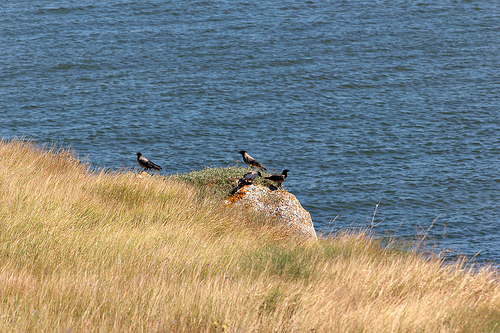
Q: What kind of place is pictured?
A: It is a field.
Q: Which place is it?
A: It is a field.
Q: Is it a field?
A: Yes, it is a field.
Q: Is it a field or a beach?
A: It is a field.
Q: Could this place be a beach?
A: No, it is a field.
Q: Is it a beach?
A: No, it is a field.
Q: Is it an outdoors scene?
A: Yes, it is outdoors.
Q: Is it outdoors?
A: Yes, it is outdoors.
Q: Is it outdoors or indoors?
A: It is outdoors.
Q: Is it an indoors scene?
A: No, it is outdoors.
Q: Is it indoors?
A: No, it is outdoors.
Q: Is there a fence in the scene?
A: No, there are no fences.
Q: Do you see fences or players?
A: No, there are no fences or players.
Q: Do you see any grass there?
A: Yes, there is grass.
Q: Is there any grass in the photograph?
A: Yes, there is grass.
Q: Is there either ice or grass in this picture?
A: Yes, there is grass.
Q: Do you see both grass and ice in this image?
A: No, there is grass but no ice.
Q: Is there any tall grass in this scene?
A: Yes, there is tall grass.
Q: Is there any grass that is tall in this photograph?
A: Yes, there is tall grass.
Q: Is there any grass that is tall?
A: Yes, there is grass that is tall.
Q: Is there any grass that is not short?
A: Yes, there is tall grass.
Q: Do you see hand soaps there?
A: No, there are no hand soaps.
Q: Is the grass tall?
A: Yes, the grass is tall.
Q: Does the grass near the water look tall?
A: Yes, the grass is tall.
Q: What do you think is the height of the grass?
A: The grass is tall.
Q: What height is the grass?
A: The grass is tall.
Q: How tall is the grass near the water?
A: The grass is tall.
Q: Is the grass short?
A: No, the grass is tall.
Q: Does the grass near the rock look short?
A: No, the grass is tall.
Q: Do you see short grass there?
A: No, there is grass but it is tall.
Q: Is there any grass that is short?
A: No, there is grass but it is tall.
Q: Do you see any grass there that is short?
A: No, there is grass but it is tall.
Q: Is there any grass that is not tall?
A: No, there is grass but it is tall.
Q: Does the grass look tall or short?
A: The grass is tall.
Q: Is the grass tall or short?
A: The grass is tall.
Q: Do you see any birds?
A: Yes, there is a bird.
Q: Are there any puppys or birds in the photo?
A: Yes, there is a bird.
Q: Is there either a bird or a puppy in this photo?
A: Yes, there is a bird.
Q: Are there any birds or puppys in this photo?
A: Yes, there is a bird.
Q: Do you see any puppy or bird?
A: Yes, there is a bird.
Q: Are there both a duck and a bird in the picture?
A: No, there is a bird but no ducks.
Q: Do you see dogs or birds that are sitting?
A: Yes, the bird is sitting.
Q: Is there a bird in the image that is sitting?
A: Yes, there is a bird that is sitting.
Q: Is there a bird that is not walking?
A: Yes, there is a bird that is sitting.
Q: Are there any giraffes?
A: No, there are no giraffes.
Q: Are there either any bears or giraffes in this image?
A: No, there are no giraffes or bears.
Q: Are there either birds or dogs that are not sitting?
A: No, there is a bird but it is sitting.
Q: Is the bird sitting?
A: Yes, the bird is sitting.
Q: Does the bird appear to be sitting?
A: Yes, the bird is sitting.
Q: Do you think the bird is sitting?
A: Yes, the bird is sitting.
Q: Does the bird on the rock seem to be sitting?
A: Yes, the bird is sitting.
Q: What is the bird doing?
A: The bird is sitting.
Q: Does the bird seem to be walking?
A: No, the bird is sitting.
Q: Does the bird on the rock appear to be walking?
A: No, the bird is sitting.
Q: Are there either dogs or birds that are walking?
A: No, there is a bird but it is sitting.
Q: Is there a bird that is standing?
A: No, there is a bird but it is sitting.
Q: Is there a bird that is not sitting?
A: No, there is a bird but it is sitting.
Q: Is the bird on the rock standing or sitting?
A: The bird is sitting.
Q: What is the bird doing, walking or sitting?
A: The bird is sitting.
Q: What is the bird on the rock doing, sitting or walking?
A: The bird is sitting.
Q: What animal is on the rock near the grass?
A: The bird is on the rock.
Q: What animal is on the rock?
A: The bird is on the rock.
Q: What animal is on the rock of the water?
A: The animal is a bird.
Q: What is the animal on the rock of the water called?
A: The animal is a bird.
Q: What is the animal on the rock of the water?
A: The animal is a bird.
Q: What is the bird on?
A: The bird is on the rock.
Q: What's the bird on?
A: The bird is on the rock.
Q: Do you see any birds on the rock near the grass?
A: Yes, there is a bird on the rock.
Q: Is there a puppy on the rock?
A: No, there is a bird on the rock.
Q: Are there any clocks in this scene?
A: No, there are no clocks.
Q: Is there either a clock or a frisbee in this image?
A: No, there are no clocks or frisbees.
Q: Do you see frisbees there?
A: No, there are no frisbees.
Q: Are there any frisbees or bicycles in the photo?
A: No, there are no frisbees or bicycles.